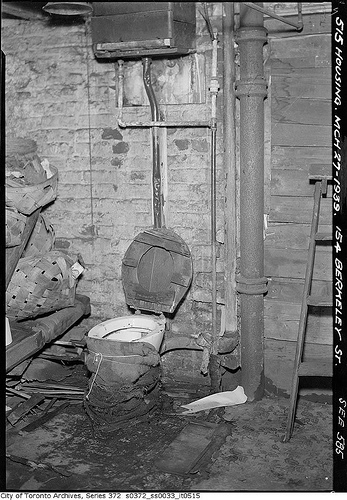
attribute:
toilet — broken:
[91, 219, 186, 418]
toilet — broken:
[76, 217, 184, 440]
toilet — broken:
[74, 218, 194, 425]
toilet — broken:
[70, 225, 181, 424]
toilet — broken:
[72, 199, 184, 416]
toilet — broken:
[72, 213, 203, 420]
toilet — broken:
[90, 232, 187, 435]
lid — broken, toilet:
[112, 222, 188, 319]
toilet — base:
[78, 312, 166, 428]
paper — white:
[180, 387, 255, 417]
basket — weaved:
[11, 254, 105, 320]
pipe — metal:
[239, 58, 269, 396]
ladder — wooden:
[309, 177, 332, 417]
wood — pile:
[19, 365, 68, 418]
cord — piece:
[95, 351, 141, 364]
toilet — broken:
[93, 233, 197, 421]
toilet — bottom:
[95, 226, 198, 434]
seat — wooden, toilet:
[109, 230, 201, 321]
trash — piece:
[183, 384, 270, 424]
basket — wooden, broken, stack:
[23, 272, 79, 306]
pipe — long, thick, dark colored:
[225, 4, 279, 402]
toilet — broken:
[87, 227, 189, 413]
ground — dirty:
[7, 380, 331, 488]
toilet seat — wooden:
[118, 224, 196, 324]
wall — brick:
[2, 21, 239, 355]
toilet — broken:
[81, 227, 202, 403]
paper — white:
[176, 375, 249, 421]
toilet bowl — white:
[84, 310, 168, 398]